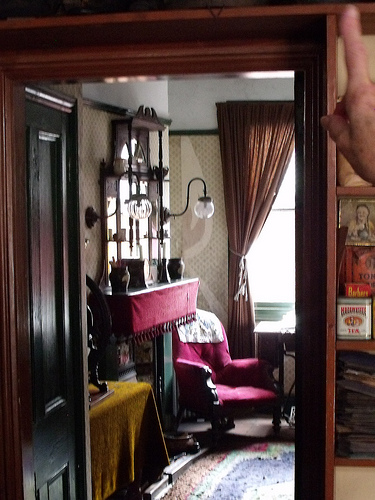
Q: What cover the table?
A: Dark mustard colored table cloth.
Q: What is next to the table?
A: Fireplace.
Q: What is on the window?
A: Brown curtain.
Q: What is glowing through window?
A: Light.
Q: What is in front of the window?
A: Red chair with cloth on back.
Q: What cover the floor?
A: A rug.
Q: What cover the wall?
A: Tan wallpaper.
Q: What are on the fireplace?
A: Lamps.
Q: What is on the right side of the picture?
A: A person's fingers.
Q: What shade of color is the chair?
A: Red.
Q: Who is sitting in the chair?
A: There is no one in the chair.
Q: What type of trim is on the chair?
A: Wood.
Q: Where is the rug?
A: On the parlor floor.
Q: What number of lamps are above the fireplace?
A: 2.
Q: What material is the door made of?
A: Wood.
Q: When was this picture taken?
A: Daytime.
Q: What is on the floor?
A: A rug.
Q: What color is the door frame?
A: Brown.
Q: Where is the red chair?
A: By the window.